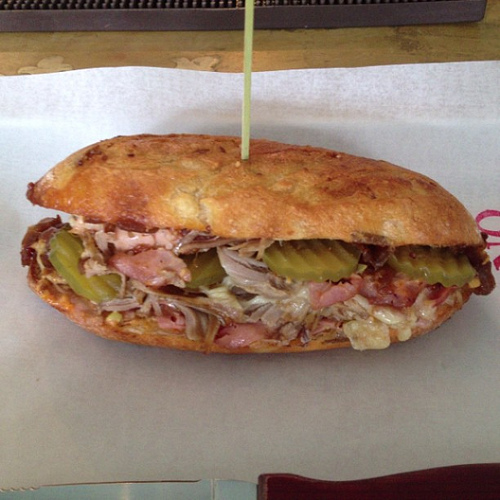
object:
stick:
[239, 0, 254, 159]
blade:
[0, 477, 257, 499]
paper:
[7, 76, 476, 497]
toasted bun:
[24, 132, 484, 248]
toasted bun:
[26, 220, 478, 335]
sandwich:
[20, 132, 492, 362]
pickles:
[266, 240, 357, 283]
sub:
[49, 108, 483, 342]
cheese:
[363, 299, 412, 348]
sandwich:
[19, 133, 496, 355]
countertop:
[0, 364, 492, 463]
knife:
[12, 462, 500, 500]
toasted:
[59, 125, 378, 200]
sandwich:
[266, 244, 358, 284]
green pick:
[241, 0, 251, 160]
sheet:
[364, 80, 486, 150]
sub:
[113, 185, 345, 355]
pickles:
[36, 229, 485, 301]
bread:
[24, 124, 489, 251]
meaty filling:
[26, 212, 492, 341]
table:
[0, 0, 500, 77]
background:
[425, 365, 487, 426]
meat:
[74, 225, 465, 329]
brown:
[80, 132, 481, 243]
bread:
[24, 132, 495, 356]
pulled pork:
[310, 277, 423, 310]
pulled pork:
[107, 230, 192, 288]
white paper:
[52, 356, 367, 460]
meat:
[21, 202, 483, 346]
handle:
[257, 462, 500, 494]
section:
[275, 404, 442, 458]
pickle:
[48, 230, 122, 304]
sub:
[22, 133, 475, 348]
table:
[6, 25, 484, 479]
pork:
[308, 268, 451, 310]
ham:
[308, 282, 358, 307]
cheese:
[68, 232, 196, 323]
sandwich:
[42, 132, 429, 353]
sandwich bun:
[73, 130, 424, 280]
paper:
[91, 65, 500, 135]